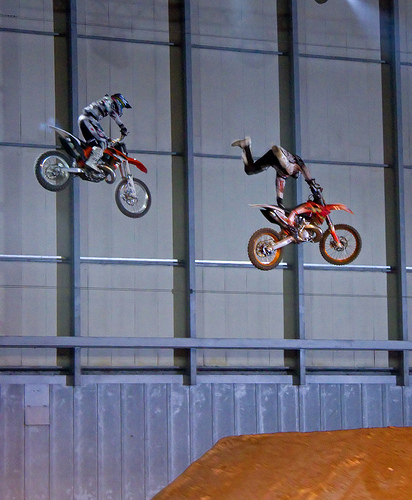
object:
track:
[148, 425, 410, 498]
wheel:
[319, 224, 362, 266]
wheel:
[113, 174, 153, 219]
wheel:
[34, 146, 74, 189]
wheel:
[246, 226, 286, 271]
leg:
[242, 146, 272, 176]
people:
[76, 91, 133, 174]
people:
[227, 134, 323, 210]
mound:
[142, 419, 409, 498]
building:
[0, 0, 411, 500]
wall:
[0, 0, 411, 382]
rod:
[168, 2, 192, 368]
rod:
[50, 7, 71, 389]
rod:
[274, 7, 304, 384]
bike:
[34, 117, 151, 220]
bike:
[246, 177, 363, 271]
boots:
[84, 147, 103, 173]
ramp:
[143, 424, 410, 498]